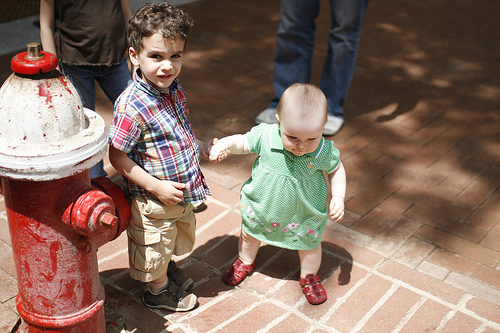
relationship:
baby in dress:
[207, 82, 349, 310] [245, 127, 322, 242]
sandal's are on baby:
[219, 257, 328, 304] [207, 82, 349, 310]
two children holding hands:
[105, 0, 348, 314] [196, 132, 235, 169]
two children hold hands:
[105, 0, 348, 314] [196, 132, 235, 169]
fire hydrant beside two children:
[0, 39, 136, 332] [105, 0, 348, 314]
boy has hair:
[104, 2, 212, 317] [118, 1, 196, 52]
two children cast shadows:
[105, 0, 348, 314] [95, 232, 350, 332]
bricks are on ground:
[346, 183, 499, 324] [19, 27, 491, 325]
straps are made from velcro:
[166, 279, 188, 300] [169, 290, 175, 295]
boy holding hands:
[104, 2, 212, 317] [196, 132, 235, 169]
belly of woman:
[74, 13, 128, 48] [38, 1, 141, 100]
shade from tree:
[206, 6, 500, 120] [458, 4, 499, 26]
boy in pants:
[104, 2, 212, 317] [126, 195, 197, 282]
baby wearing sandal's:
[207, 82, 349, 310] [219, 257, 328, 304]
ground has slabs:
[19, 27, 491, 325] [355, 190, 415, 241]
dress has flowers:
[245, 127, 322, 242] [238, 208, 322, 243]